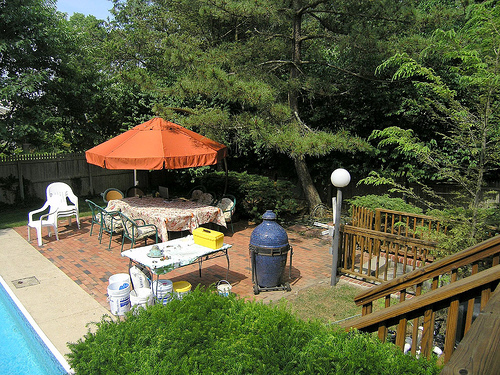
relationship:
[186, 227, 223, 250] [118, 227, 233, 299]
toolbox on table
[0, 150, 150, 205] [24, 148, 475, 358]
privacy fence in backyard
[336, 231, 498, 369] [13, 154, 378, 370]
stairs in backyard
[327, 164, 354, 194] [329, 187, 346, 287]
ball light on post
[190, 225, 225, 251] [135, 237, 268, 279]
box on table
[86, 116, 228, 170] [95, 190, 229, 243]
umbrella over dining table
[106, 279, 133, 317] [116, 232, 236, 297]
bucket under table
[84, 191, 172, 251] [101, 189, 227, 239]
chairs around dining table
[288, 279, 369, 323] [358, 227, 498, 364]
grass beside stairs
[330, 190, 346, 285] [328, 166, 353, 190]
post with ball light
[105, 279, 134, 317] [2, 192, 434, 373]
bucket on ground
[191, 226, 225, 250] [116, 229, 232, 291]
toolbox on table